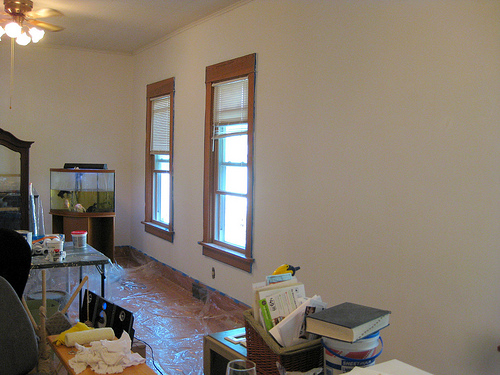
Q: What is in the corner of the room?
A: Fish tank.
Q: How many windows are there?
A: Two.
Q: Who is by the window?
A: No one.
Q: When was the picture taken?
A: Daytime.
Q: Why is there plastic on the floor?
A: Protection.